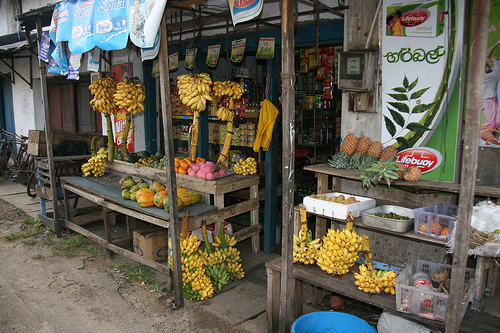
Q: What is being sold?
A: Fruit.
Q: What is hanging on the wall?
A: Advertisements.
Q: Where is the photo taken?
A: At a store.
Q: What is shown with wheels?
A: A bicycle.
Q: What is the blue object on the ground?
A: A bucket.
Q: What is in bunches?
A: Bananas.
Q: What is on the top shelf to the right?
A: Pineapple.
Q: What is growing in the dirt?
A: Patches of grass.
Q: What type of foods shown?
A: Fruit.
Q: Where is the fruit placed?
A: Stands.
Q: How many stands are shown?
A: Two.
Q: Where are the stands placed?
A: Street.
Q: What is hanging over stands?
A: Advertisements.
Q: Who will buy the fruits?
A: Customers.